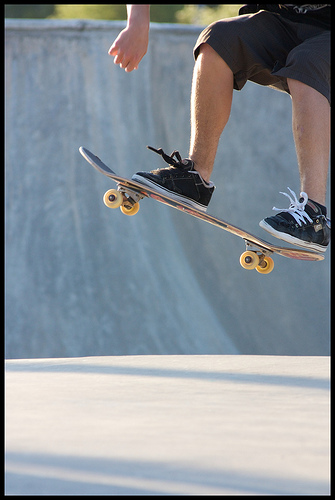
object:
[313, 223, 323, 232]
tag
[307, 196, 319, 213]
tag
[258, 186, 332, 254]
shoe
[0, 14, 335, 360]
concrete barrier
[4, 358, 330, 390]
shadow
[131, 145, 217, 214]
shoe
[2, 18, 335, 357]
wall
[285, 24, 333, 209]
leg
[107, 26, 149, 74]
hand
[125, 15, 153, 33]
wrist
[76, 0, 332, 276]
skating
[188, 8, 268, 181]
legs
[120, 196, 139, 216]
wheel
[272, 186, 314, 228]
lace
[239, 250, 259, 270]
wheel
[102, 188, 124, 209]
wheel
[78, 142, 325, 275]
skateboard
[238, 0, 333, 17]
t-shirt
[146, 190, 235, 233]
accents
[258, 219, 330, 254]
bottom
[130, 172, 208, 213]
bottom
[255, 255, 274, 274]
wheel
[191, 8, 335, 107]
shorts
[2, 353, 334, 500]
ground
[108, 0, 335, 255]
man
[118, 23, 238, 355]
downward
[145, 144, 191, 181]
lace